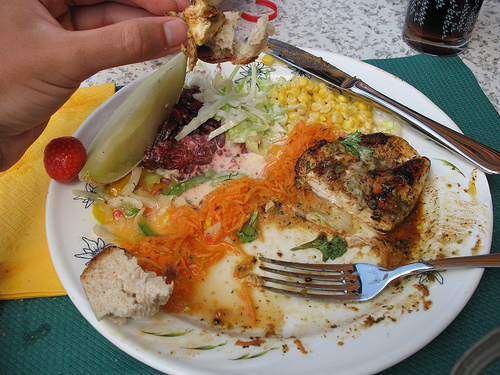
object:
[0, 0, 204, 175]
hand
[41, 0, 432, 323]
food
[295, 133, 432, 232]
chicken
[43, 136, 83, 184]
strawberry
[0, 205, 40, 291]
napkin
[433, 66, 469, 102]
mat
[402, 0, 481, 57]
glass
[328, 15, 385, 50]
table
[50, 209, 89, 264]
plate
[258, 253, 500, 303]
fork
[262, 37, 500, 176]
knife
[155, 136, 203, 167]
pickle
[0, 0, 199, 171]
person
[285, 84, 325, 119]
corn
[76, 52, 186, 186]
melon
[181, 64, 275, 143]
cabbage